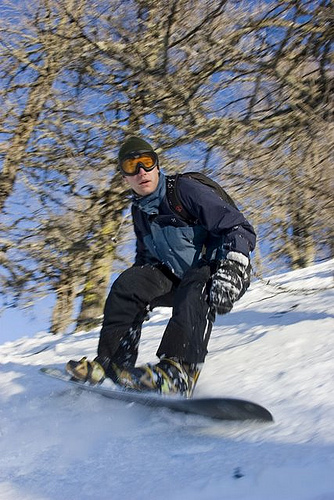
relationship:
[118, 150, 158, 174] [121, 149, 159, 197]
goggles on a mans man's face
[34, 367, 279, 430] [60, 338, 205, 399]
snowboard under a mans feet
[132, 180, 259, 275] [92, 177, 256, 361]
jacket on a mans body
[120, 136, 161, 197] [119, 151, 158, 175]
head with goggles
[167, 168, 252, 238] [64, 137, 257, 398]
backpack on a skier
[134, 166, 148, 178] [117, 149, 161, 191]
nose on man's face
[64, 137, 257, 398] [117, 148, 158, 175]
skier wearing googles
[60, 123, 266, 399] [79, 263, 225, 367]
skier wearing pants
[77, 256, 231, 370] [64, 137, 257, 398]
pants on a skier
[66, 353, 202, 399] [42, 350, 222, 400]
boots on a feet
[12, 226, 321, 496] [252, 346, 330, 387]
hill with snow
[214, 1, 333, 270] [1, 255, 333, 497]
tree on hill